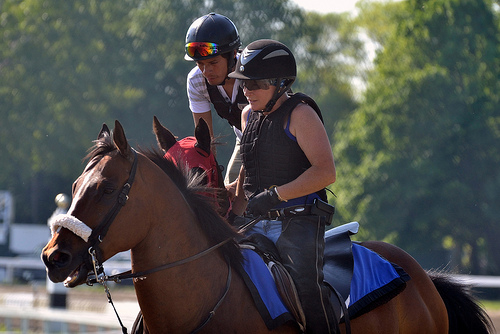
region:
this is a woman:
[237, 97, 297, 159]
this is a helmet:
[229, 57, 266, 94]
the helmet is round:
[226, 60, 282, 72]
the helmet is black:
[272, 58, 298, 129]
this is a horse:
[110, 172, 130, 199]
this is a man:
[180, 64, 266, 154]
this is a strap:
[132, 258, 180, 297]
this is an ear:
[87, 128, 145, 168]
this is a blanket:
[239, 272, 278, 308]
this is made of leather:
[195, 315, 228, 331]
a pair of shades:
[232, 78, 272, 91]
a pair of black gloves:
[240, 181, 285, 216]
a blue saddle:
[231, 225, 404, 331]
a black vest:
[201, 80, 333, 214]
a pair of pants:
[244, 194, 338, 333]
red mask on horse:
[157, 134, 223, 193]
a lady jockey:
[226, 38, 338, 333]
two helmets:
[182, 10, 299, 85]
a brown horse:
[38, 109, 498, 329]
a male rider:
[179, 8, 249, 148]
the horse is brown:
[82, 232, 444, 329]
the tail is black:
[409, 252, 491, 330]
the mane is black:
[139, 151, 255, 288]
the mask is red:
[171, 130, 229, 197]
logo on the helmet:
[232, 44, 294, 85]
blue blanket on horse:
[240, 237, 405, 332]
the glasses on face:
[232, 71, 288, 96]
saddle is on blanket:
[240, 227, 400, 304]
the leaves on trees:
[300, 42, 498, 274]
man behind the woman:
[163, 12, 335, 279]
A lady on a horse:
[37, 42, 430, 312]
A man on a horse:
[97, 2, 238, 192]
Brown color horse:
[46, 130, 432, 332]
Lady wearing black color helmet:
[233, 33, 298, 123]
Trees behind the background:
[23, 15, 153, 138]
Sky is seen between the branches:
[316, 7, 388, 113]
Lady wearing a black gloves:
[230, 47, 322, 252]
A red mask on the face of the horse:
[143, 115, 229, 205]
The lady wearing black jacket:
[235, 32, 370, 183]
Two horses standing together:
[42, 101, 446, 332]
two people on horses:
[143, 13, 384, 328]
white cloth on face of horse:
[35, 208, 105, 240]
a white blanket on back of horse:
[236, 217, 438, 328]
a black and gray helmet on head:
[220, 39, 315, 105]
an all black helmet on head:
[175, 3, 254, 87]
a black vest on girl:
[221, 87, 358, 241]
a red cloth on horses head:
[157, 107, 227, 217]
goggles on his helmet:
[164, 32, 234, 67]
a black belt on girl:
[243, 191, 343, 234]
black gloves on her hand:
[222, 170, 299, 220]